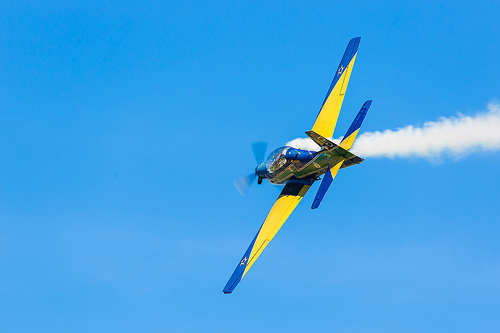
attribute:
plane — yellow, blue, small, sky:
[222, 36, 374, 294]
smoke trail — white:
[349, 114, 498, 166]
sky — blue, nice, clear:
[0, 4, 497, 332]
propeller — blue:
[233, 140, 265, 194]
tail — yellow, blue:
[307, 132, 362, 165]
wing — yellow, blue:
[223, 185, 311, 293]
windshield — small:
[263, 147, 287, 173]